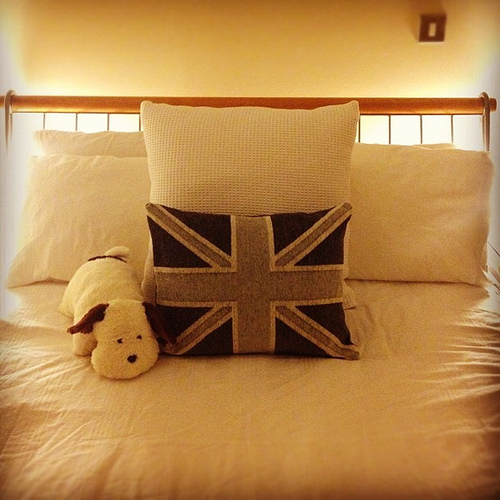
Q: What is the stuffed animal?
A: Dog.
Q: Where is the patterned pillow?
A: On the bed.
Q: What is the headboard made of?
A: Metal and wood.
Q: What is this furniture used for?
A: To sleep in.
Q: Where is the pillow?
A: In the bed.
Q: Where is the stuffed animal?
A: On the bed.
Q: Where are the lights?
A: On the headboard.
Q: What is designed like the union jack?
A: The large pillow in the center.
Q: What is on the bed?
A: The stuffed dog.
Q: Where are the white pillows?
A: Behind the british pillow.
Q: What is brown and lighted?
A: The headboard.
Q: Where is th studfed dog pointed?
A: Forward.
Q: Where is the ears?
A: On the dog.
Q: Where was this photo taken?
A: In a bedroom.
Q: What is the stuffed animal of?
A: A dog.